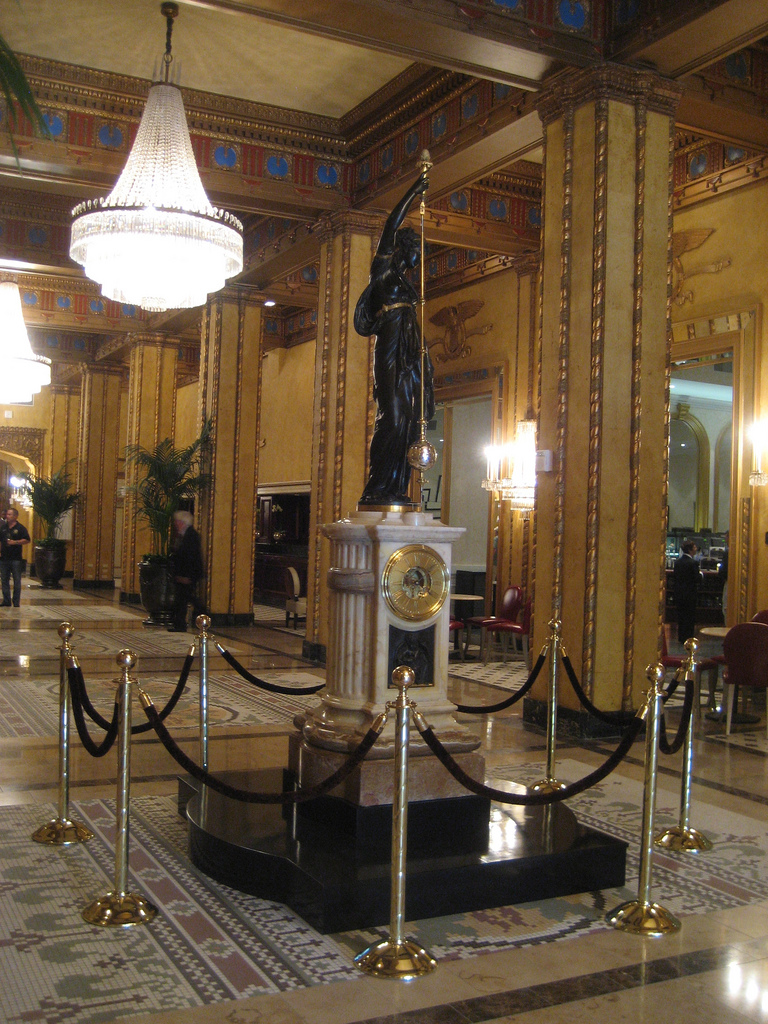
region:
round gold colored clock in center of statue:
[384, 535, 455, 632]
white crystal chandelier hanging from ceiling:
[71, 83, 249, 301]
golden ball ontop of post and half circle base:
[364, 661, 423, 990]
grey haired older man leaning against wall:
[170, 506, 201, 632]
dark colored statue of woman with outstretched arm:
[355, 174, 436, 505]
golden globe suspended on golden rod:
[397, 415, 470, 487]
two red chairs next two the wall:
[482, 584, 541, 655]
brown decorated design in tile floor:
[0, 909, 47, 958]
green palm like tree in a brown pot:
[23, 463, 80, 591]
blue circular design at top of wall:
[260, 140, 292, 190]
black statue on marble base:
[293, 144, 476, 822]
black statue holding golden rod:
[348, 142, 446, 509]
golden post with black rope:
[357, 657, 676, 987]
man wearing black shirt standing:
[0, 503, 30, 607]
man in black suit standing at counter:
[669, 539, 706, 652]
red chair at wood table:
[653, 617, 727, 716]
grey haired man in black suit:
[162, 506, 206, 634]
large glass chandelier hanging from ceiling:
[65, 2, 247, 317]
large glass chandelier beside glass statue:
[63, 72, 457, 513]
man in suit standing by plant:
[126, 427, 214, 627]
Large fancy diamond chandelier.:
[68, 70, 246, 313]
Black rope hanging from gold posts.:
[393, 661, 667, 941]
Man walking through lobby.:
[164, 503, 208, 634]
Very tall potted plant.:
[27, 468, 80, 591]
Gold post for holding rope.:
[371, 666, 434, 984]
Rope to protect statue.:
[382, 664, 681, 945]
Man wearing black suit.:
[668, 534, 708, 660]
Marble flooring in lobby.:
[325, 977, 741, 1016]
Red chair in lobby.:
[472, 586, 529, 678]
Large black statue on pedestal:
[351, 147, 472, 515]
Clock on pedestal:
[369, 536, 456, 639]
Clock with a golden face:
[364, 532, 464, 635]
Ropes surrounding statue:
[30, 606, 727, 913]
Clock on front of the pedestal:
[311, 500, 474, 738]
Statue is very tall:
[318, 162, 493, 524]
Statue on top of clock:
[345, 158, 468, 506]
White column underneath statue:
[314, 501, 490, 725]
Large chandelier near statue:
[49, 77, 288, 388]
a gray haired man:
[162, 506, 205, 633]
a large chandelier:
[68, 78, 244, 313]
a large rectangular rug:
[0, 755, 766, 1018]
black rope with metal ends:
[408, 697, 647, 805]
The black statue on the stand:
[360, 178, 440, 502]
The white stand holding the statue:
[319, 507, 466, 728]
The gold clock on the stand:
[384, 542, 448, 620]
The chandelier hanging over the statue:
[71, 55, 247, 317]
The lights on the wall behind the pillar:
[483, 423, 537, 511]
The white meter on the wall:
[532, 445, 553, 474]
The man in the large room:
[2, 505, 32, 608]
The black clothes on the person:
[2, 519, 29, 602]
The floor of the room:
[1, 572, 766, 1022]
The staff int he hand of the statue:
[410, 143, 440, 510]